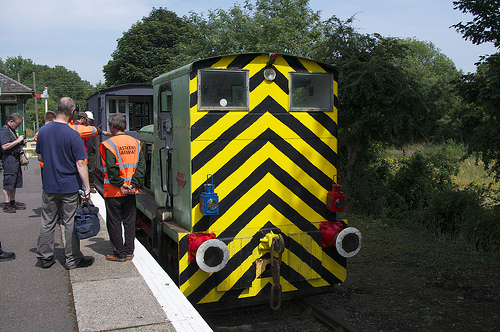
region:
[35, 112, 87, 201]
the shirt is blue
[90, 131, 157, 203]
the vest is orange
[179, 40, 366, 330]
the train is yellow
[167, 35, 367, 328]
the train is black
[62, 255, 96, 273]
the shoe is black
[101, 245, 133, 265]
the shoe is brown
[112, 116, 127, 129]
the man has hair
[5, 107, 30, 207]
the man is looking down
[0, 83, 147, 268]
the people are standing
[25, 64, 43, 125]
the pole is wooden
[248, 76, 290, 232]
Yellow and black pattern on back of train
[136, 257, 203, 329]
White paint on edge of train stationplatform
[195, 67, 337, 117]
Two windows at top of train caboose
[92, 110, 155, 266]
Man wearing orange safety vest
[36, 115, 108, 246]
Person holding a blue backpack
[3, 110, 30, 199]
Man looking at a camera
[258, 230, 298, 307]
Hitch on back of train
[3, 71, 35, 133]
Green and brown building at train station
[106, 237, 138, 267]
Person's orange shoes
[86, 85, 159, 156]
Blue train car behind station worker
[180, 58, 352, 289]
Black and yellow front of train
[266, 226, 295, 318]
Chain hanging from train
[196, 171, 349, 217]
Headlights look like lanterns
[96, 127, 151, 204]
Man in orange vest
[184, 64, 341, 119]
Train windows are square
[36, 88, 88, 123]
Man is balding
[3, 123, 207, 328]
Train platform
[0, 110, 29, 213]
Man wearing cargo shorts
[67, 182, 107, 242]
Man is holding blue bag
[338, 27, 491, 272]
Trees and bushes on far side of train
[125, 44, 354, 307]
a green train engine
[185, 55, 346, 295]
yellow and black stripes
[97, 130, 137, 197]
an orange safety vest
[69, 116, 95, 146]
an orange safety vest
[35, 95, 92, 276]
a man standing on pavement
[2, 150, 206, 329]
a train boarding platform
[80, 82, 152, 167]
a train passenger car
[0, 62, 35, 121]
a train station shelter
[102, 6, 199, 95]
a tall green tree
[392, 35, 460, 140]
a tall green tree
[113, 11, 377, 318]
small train with caution wall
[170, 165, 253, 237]
blue light lantern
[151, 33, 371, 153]
two windows on the train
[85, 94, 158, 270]
man wearitn orange safety vest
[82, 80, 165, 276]
man wearing black pants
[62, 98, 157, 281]
man wearing brown leather shoes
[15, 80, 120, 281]
man wearing blue tee shirt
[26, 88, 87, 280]
man wearing gray pants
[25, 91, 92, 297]
man with gray hair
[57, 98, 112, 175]
person wearing white safety helmet